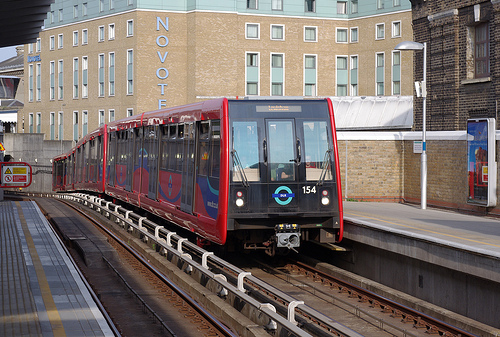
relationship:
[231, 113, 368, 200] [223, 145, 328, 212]
safety glass and extinguisher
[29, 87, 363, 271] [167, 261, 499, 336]
train on track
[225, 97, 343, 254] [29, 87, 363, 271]
front of train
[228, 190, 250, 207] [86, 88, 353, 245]
headlight left of train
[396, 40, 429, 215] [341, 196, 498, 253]
pole on sidewalk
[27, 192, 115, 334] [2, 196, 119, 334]
white line near walk way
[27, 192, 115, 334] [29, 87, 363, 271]
white line near train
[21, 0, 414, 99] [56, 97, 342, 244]
brown/blue wall near train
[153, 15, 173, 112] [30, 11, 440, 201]
novot on building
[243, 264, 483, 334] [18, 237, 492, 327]
track on ground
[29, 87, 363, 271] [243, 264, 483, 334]
train on track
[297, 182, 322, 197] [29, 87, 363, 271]
154 on train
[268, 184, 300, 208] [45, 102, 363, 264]
emblem on train